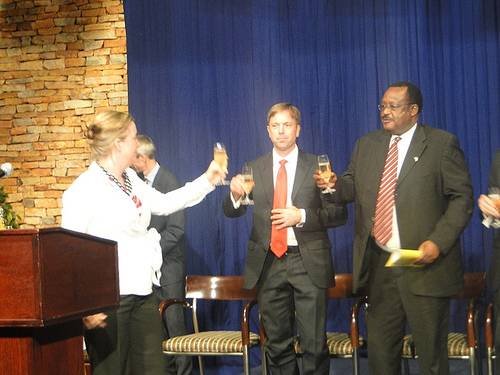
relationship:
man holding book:
[315, 85, 467, 371] [347, 231, 444, 274]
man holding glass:
[221, 99, 348, 374] [238, 162, 255, 207]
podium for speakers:
[0, 223, 118, 373] [50, 84, 480, 367]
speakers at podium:
[50, 84, 480, 367] [0, 223, 118, 373]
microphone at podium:
[0, 160, 14, 187] [0, 223, 118, 373]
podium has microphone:
[0, 223, 118, 373] [0, 160, 14, 187]